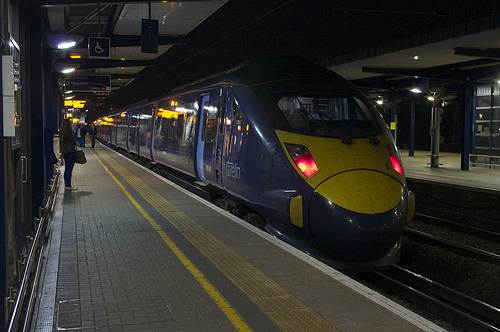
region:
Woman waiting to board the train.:
[41, 107, 98, 195]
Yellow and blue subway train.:
[102, 50, 435, 278]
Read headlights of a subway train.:
[262, 123, 437, 185]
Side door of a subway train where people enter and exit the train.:
[170, 87, 244, 199]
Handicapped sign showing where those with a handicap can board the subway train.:
[61, 26, 142, 79]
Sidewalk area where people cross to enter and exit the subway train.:
[59, 181, 379, 329]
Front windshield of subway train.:
[260, 86, 405, 154]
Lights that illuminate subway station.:
[25, 24, 110, 96]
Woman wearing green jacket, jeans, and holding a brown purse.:
[45, 81, 97, 201]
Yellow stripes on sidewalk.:
[107, 180, 319, 330]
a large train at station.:
[85, 56, 451, 284]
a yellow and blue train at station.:
[98, 55, 423, 280]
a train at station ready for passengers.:
[50, 73, 443, 256]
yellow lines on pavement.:
[152, 208, 235, 305]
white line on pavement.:
[318, 260, 420, 317]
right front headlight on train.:
[284, 135, 326, 183]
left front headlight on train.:
[376, 143, 414, 189]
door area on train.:
[180, 86, 245, 196]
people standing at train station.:
[57, 106, 110, 198]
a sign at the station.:
[77, 26, 126, 71]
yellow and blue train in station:
[98, 45, 424, 259]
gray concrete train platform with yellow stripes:
[49, 128, 439, 328]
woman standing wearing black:
[57, 112, 96, 203]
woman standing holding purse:
[53, 115, 90, 196]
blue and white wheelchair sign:
[88, 32, 118, 54]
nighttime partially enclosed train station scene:
[3, 0, 498, 328]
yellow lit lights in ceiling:
[56, 45, 97, 150]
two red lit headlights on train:
[283, 132, 405, 182]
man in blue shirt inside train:
[308, 91, 340, 126]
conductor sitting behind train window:
[276, 91, 380, 126]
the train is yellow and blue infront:
[285, 134, 443, 259]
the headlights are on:
[284, 149, 419, 202]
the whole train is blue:
[127, 102, 337, 236]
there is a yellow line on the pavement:
[133, 206, 215, 281]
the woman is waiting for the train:
[51, 134, 92, 183]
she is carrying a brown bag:
[68, 147, 102, 169]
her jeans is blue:
[53, 155, 89, 190]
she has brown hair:
[55, 114, 79, 131]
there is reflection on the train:
[113, 123, 210, 173]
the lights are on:
[48, 35, 82, 72]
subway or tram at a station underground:
[49, 34, 441, 296]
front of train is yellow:
[275, 122, 419, 237]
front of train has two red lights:
[281, 142, 409, 187]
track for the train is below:
[388, 261, 480, 308]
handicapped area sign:
[75, 34, 113, 69]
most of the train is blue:
[107, 94, 276, 207]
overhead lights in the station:
[50, 22, 87, 122]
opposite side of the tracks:
[412, 69, 491, 229]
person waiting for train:
[48, 109, 84, 206]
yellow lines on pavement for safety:
[97, 171, 227, 309]